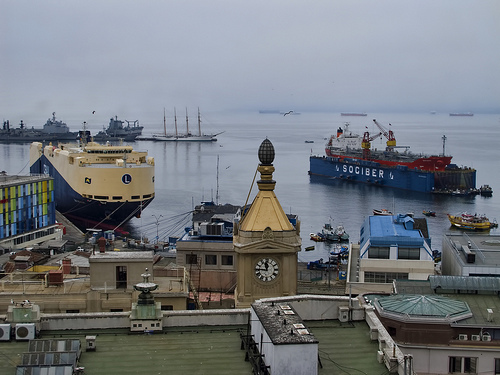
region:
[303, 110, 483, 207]
a large ship on the water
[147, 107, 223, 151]
a white sail boat on the ocean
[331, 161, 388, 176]
white lettering on the side of a blue ship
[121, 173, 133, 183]
blue logo on the tan front of a ship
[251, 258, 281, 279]
white face of the clock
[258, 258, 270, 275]
black hands of the clock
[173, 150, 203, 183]
calm black water of the ocean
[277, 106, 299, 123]
a bird flying over the port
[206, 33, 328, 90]
cloudy white skies over the ocean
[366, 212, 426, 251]
blue roof of a white building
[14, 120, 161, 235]
A cargo boat is docked at the pier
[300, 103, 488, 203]
A boat is inside the shipyard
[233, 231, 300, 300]
A clock is on the tower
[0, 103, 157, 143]
Grey boats are on the water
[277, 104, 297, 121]
A seagull is flying in the air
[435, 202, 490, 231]
The boat is yellow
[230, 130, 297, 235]
A lighthouse is on the pier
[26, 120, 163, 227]
The boat is tan and blue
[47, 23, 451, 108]
The sky is cloudy and overcast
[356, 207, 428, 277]
The building has a blue roof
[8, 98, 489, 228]
water with boats in it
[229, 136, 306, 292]
tower structure with clock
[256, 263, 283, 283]
clock on the face of tower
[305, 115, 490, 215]
boat in the water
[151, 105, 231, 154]
boat in the water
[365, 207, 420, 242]
blue roof on top of building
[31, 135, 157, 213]
tan and blue boat in water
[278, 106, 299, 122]
bird in the air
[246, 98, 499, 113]
land in the distance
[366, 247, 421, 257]
windows on the building side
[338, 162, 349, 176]
The letter is white.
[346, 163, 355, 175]
The letter is white.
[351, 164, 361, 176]
The letter is white.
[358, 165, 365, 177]
The letter is white.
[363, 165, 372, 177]
The letter is white.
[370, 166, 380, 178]
The letter is white.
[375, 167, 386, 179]
The letter is white.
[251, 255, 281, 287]
The face of the clock is round.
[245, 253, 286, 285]
The hour and minute hand on the clock is black.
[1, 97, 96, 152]
The ship is in the water.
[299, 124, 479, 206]
a large blue and red boat in the water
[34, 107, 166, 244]
a large yellow and blue boat in the water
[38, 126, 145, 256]
a boat tied to a boat dock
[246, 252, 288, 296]
a large clock on a building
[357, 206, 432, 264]
a blue roof on a building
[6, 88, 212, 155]
three boats in a row on the water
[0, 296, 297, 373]
the roof of a building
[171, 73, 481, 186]
a ocean view with boats in the water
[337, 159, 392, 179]
white letters painted on a boat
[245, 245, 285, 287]
a black and white clock on a building